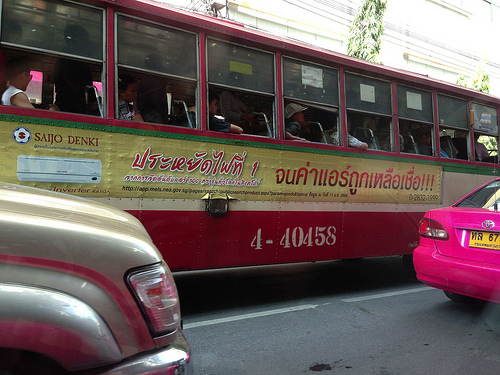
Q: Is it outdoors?
A: Yes, it is outdoors.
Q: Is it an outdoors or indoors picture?
A: It is outdoors.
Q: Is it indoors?
A: No, it is outdoors.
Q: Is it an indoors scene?
A: No, it is outdoors.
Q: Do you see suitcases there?
A: No, there are no suitcases.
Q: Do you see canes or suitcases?
A: No, there are no suitcases or canes.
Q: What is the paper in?
A: The paper is in the window.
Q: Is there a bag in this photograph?
A: No, there are no bags.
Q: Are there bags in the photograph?
A: No, there are no bags.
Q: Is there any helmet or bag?
A: No, there are no bags or helmets.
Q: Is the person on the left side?
A: Yes, the person is on the left of the image.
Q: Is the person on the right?
A: No, the person is on the left of the image.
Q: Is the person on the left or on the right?
A: The person is on the left of the image.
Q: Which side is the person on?
A: The person is on the left of the image.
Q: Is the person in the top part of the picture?
A: Yes, the person is in the top of the image.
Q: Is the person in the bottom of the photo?
A: No, the person is in the top of the image.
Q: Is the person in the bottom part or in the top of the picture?
A: The person is in the top of the image.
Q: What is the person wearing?
A: The person is wearing a shirt.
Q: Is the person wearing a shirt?
A: Yes, the person is wearing a shirt.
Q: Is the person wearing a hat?
A: No, the person is wearing a shirt.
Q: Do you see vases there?
A: No, there are no vases.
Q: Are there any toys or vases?
A: No, there are no vases or toys.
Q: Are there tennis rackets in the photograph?
A: No, there are no tennis rackets.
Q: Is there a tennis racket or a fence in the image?
A: No, there are no rackets or fences.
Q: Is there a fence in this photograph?
A: No, there are no fences.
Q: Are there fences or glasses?
A: No, there are no fences or glasses.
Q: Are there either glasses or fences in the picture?
A: No, there are no fences or glasses.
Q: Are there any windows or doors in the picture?
A: Yes, there is a window.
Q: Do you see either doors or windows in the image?
A: Yes, there is a window.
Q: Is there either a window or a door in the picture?
A: Yes, there is a window.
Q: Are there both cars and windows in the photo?
A: Yes, there are both a window and a car.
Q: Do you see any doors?
A: No, there are no doors.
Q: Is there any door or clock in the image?
A: No, there are no doors or clocks.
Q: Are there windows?
A: Yes, there is a window.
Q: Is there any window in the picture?
A: Yes, there is a window.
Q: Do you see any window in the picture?
A: Yes, there is a window.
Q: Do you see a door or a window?
A: Yes, there is a window.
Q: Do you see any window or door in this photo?
A: Yes, there is a window.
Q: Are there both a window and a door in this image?
A: No, there is a window but no doors.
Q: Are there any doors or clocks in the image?
A: No, there are no doors or clocks.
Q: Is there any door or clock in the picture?
A: No, there are no doors or clocks.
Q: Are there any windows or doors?
A: Yes, there is a window.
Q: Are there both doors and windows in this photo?
A: No, there is a window but no doors.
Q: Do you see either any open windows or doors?
A: Yes, there is an open window.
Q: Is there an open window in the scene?
A: Yes, there is an open window.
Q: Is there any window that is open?
A: Yes, there is a window that is open.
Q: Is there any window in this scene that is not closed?
A: Yes, there is a open window.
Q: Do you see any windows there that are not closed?
A: Yes, there is a open window.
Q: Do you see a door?
A: No, there are no doors.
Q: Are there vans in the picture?
A: No, there are no vans.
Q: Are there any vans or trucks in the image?
A: No, there are no vans or trucks.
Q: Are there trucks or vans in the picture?
A: No, there are no vans or trucks.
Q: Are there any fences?
A: No, there are no fences.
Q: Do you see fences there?
A: No, there are no fences.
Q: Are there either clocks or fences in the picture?
A: No, there are no fences or clocks.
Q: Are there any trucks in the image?
A: No, there are no trucks.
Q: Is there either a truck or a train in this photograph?
A: No, there are no trucks or trains.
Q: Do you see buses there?
A: Yes, there is a bus.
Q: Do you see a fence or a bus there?
A: Yes, there is a bus.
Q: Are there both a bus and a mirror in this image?
A: No, there is a bus but no mirrors.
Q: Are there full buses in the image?
A: Yes, there is a full bus.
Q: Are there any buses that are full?
A: Yes, there is a bus that is full.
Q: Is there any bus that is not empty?
A: Yes, there is an full bus.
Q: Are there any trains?
A: No, there are no trains.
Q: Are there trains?
A: No, there are no trains.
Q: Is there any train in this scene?
A: No, there are no trains.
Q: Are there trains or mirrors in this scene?
A: No, there are no trains or mirrors.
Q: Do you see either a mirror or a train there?
A: No, there are no trains or mirrors.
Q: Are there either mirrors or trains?
A: No, there are no trains or mirrors.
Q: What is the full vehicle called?
A: The vehicle is a bus.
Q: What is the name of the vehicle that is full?
A: The vehicle is a bus.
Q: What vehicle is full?
A: The vehicle is a bus.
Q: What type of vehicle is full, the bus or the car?
A: The bus is full.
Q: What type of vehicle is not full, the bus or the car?
A: The car is not full.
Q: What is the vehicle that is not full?
A: The vehicle is a car.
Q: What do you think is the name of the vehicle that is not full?
A: The vehicle is a car.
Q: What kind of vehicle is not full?
A: The vehicle is a car.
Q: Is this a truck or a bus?
A: This is a bus.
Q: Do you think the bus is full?
A: Yes, the bus is full.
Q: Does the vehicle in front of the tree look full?
A: Yes, the bus is full.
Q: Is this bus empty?
A: No, the bus is full.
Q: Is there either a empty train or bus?
A: No, there is a bus but it is full.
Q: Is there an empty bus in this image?
A: No, there is a bus but it is full.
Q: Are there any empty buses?
A: No, there is a bus but it is full.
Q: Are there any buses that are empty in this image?
A: No, there is a bus but it is full.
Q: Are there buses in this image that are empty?
A: No, there is a bus but it is full.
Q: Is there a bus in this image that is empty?
A: No, there is a bus but it is full.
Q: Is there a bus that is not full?
A: No, there is a bus but it is full.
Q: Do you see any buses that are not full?
A: No, there is a bus but it is full.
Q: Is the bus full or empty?
A: The bus is full.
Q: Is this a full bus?
A: Yes, this is a full bus.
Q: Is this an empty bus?
A: No, this is a full bus.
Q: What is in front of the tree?
A: The bus is in front of the tree.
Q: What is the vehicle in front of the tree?
A: The vehicle is a bus.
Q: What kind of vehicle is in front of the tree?
A: The vehicle is a bus.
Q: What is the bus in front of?
A: The bus is in front of the tree.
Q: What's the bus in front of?
A: The bus is in front of the tree.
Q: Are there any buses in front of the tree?
A: Yes, there is a bus in front of the tree.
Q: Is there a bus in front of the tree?
A: Yes, there is a bus in front of the tree.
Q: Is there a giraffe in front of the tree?
A: No, there is a bus in front of the tree.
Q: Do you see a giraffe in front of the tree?
A: No, there is a bus in front of the tree.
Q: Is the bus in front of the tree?
A: Yes, the bus is in front of the tree.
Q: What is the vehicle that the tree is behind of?
A: The vehicle is a bus.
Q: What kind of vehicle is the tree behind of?
A: The tree is behind the bus.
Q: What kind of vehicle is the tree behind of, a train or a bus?
A: The tree is behind a bus.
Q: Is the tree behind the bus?
A: Yes, the tree is behind the bus.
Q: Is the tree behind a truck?
A: No, the tree is behind the bus.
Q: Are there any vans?
A: No, there are no vans.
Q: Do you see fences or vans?
A: No, there are no vans or fences.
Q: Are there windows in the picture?
A: Yes, there is a window.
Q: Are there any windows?
A: Yes, there is a window.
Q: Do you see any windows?
A: Yes, there is a window.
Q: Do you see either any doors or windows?
A: Yes, there is a window.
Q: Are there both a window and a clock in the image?
A: No, there is a window but no clocks.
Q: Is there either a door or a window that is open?
A: Yes, the window is open.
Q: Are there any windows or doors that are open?
A: Yes, the window is open.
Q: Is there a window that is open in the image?
A: Yes, there is an open window.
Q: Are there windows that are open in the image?
A: Yes, there is an open window.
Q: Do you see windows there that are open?
A: Yes, there is a window that is open.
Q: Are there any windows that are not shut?
A: Yes, there is a open window.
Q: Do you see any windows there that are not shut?
A: Yes, there is a open window.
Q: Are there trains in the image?
A: No, there are no trains.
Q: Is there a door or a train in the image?
A: No, there are no trains or doors.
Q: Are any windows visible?
A: Yes, there is a window.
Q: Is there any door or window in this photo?
A: Yes, there is a window.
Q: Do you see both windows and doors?
A: No, there is a window but no doors.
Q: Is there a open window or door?
A: Yes, there is an open window.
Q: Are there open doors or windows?
A: Yes, there is an open window.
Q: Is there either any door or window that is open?
A: Yes, the window is open.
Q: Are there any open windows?
A: Yes, there is an open window.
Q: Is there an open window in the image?
A: Yes, there is an open window.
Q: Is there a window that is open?
A: Yes, there is a window that is open.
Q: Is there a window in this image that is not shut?
A: Yes, there is a open window.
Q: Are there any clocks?
A: No, there are no clocks.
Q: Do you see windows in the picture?
A: Yes, there is a window.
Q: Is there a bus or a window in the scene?
A: Yes, there is a window.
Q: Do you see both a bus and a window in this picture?
A: Yes, there are both a window and a bus.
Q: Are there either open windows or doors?
A: Yes, there is an open window.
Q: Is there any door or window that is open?
A: Yes, the window is open.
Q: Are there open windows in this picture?
A: Yes, there is an open window.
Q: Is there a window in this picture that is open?
A: Yes, there is a window that is open.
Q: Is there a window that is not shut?
A: Yes, there is a open window.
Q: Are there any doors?
A: No, there are no doors.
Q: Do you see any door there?
A: No, there are no doors.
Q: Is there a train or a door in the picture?
A: No, there are no doors or trains.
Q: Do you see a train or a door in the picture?
A: No, there are no doors or trains.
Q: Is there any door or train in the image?
A: No, there are no doors or trains.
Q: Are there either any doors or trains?
A: No, there are no doors or trains.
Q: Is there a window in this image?
A: Yes, there is a window.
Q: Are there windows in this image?
A: Yes, there is a window.